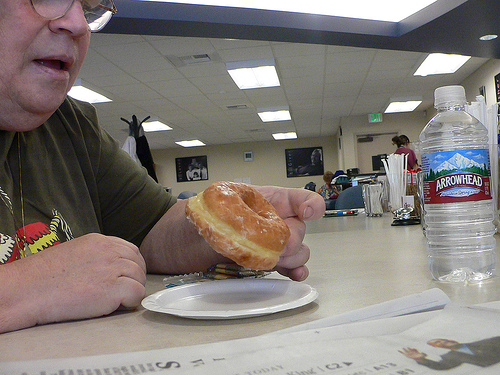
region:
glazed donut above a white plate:
[183, 178, 285, 273]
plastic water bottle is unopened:
[416, 85, 498, 285]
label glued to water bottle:
[420, 145, 493, 205]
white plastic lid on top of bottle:
[433, 84, 468, 109]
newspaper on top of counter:
[0, 282, 498, 372]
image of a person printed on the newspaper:
[395, 335, 495, 370]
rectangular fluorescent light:
[220, 56, 280, 91]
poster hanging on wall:
[281, 145, 321, 175]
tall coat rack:
[117, 112, 157, 177]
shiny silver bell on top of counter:
[388, 202, 419, 223]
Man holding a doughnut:
[150, 158, 332, 305]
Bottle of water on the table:
[404, 70, 498, 312]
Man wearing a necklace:
[3, 138, 68, 264]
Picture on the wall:
[170, 144, 215, 184]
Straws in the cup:
[372, 117, 412, 226]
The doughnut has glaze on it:
[190, 166, 335, 332]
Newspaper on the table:
[207, 333, 257, 365]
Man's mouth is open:
[22, 50, 92, 90]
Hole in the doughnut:
[230, 182, 276, 233]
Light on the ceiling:
[219, 52, 297, 104]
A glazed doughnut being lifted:
[186, 179, 290, 272]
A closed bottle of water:
[415, 81, 499, 284]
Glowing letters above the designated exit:
[366, 111, 386, 123]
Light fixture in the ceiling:
[223, 57, 285, 90]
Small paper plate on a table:
[139, 275, 329, 321]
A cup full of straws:
[381, 151, 411, 217]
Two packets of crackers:
[201, 260, 276, 283]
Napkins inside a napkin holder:
[361, 180, 386, 215]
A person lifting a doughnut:
[0, 0, 326, 334]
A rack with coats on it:
[119, 113, 160, 186]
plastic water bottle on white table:
[417, 83, 494, 283]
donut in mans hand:
[184, 173, 322, 277]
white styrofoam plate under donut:
[137, 276, 319, 323]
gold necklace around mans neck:
[12, 142, 27, 257]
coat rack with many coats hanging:
[120, 113, 160, 178]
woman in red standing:
[392, 132, 420, 172]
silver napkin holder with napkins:
[362, 182, 384, 216]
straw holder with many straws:
[383, 150, 413, 210]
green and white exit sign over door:
[366, 111, 385, 122]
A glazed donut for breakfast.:
[172, 163, 302, 285]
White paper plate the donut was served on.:
[131, 268, 321, 335]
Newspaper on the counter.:
[295, 278, 495, 370]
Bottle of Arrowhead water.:
[422, 76, 496, 297]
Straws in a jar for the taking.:
[375, 144, 412, 216]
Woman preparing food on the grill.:
[387, 125, 421, 180]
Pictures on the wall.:
[171, 136, 323, 193]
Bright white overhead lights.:
[224, 58, 296, 163]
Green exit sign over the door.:
[363, 103, 390, 132]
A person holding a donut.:
[2, 0, 337, 340]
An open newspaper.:
[1, 290, 498, 373]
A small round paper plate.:
[144, 278, 317, 315]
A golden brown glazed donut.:
[184, 182, 294, 272]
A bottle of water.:
[418, 80, 498, 285]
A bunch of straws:
[381, 147, 408, 216]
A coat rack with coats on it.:
[116, 102, 160, 177]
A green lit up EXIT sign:
[367, 113, 389, 126]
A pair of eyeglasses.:
[33, 1, 125, 33]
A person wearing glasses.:
[4, 5, 329, 335]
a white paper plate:
[113, 265, 326, 326]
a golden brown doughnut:
[176, 165, 297, 280]